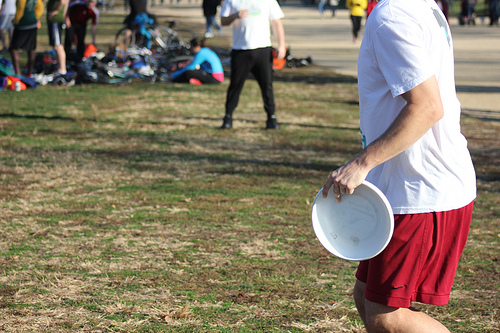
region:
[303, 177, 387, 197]
a hand grasping a white frisbee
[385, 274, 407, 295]
a black logo on red shorts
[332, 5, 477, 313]
a person wearing a white t-shirt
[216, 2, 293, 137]
a person wearing black pants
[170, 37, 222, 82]
a woman sitting on the ground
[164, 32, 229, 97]
a woman wearing a blue top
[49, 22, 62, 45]
white stripes on black shorts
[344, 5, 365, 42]
a jogger wearing a yellow jacket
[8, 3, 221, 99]
a crowd of people at the park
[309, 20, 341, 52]
the paved pathway in a park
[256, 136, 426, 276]
holding a frisbee in hand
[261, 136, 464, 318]
this man has red shorts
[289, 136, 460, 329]
the shorts have the nike logo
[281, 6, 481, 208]
the man's shirt is white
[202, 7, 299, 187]
this man's pants are black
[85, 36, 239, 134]
people are sitting down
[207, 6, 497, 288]
this man is moving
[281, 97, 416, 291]
the frisbee is round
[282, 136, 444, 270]
the frisbee is white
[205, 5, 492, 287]
these men are playing frisbee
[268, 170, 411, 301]
the Frisbee is white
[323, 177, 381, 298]
the Frisbee is white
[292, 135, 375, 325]
the Frisbee is white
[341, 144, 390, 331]
the Frisbee is white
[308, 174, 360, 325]
the Frisbee is white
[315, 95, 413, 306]
the Frisbee is white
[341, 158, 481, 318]
a man in red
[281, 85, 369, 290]
a man in red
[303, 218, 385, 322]
a man in red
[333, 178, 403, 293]
a man in red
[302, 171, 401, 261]
White frisbee in man's left hand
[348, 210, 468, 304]
Man wearing red shorts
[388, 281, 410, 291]
Black Nike swoop on red shorts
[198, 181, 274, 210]
Green grass in a yard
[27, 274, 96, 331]
Clump of brown grass in a yard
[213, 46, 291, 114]
Man wearing long black pants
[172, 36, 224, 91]
woman sitting on the grass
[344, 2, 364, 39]
Woman with a yellow shirt running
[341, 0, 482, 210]
Man wearing a white shrit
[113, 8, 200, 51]
Bicycle on the grass